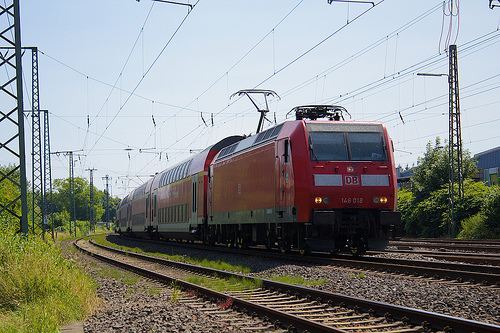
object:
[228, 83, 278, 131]
device/train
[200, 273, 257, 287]
grass patches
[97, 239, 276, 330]
rails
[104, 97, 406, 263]
train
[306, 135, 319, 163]
wipers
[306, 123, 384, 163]
windshield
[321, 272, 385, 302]
gravel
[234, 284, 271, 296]
planks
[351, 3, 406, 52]
wires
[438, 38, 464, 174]
pole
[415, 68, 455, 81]
light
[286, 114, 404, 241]
front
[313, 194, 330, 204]
headlight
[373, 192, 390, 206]
headlight